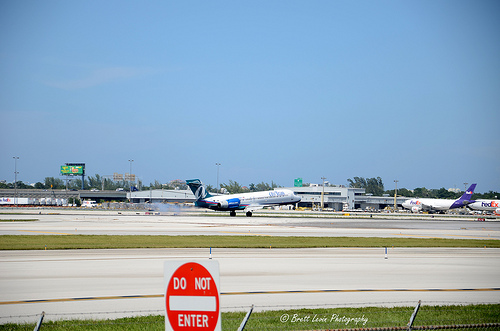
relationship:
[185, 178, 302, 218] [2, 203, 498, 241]
plane on runway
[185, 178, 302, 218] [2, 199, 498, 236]
plane on runway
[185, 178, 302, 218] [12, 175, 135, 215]
plane at airport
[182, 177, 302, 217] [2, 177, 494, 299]
plane landing at airport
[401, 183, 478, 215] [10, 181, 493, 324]
plane at airport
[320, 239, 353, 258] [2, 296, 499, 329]
edge of a fence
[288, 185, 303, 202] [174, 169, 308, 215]
plane tip of a airplane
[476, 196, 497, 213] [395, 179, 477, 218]
logo on plane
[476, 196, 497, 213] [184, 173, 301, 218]
logo on plane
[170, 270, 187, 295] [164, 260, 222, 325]
word on sign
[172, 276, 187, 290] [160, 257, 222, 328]
word on sign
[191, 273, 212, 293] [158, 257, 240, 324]
word on sign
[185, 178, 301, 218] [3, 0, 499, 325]
airplane at air terminal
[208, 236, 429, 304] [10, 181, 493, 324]
surface at airport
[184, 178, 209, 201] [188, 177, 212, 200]
design on tail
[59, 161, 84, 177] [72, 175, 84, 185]
sign on pole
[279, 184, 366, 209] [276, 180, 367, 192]
terminal with roof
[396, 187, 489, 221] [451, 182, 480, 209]
plane has purple tail